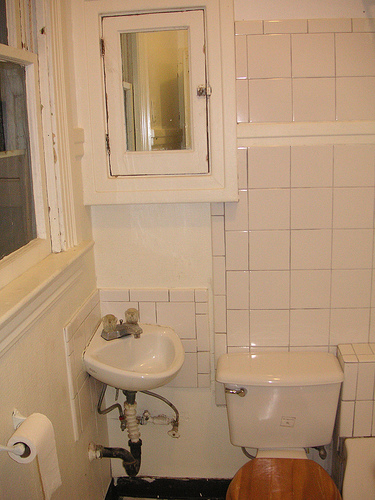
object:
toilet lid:
[226, 457, 342, 499]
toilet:
[215, 351, 343, 500]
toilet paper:
[5, 411, 63, 499]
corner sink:
[83, 316, 185, 391]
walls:
[64, 288, 212, 442]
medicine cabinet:
[71, 1, 239, 205]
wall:
[70, 1, 375, 474]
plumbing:
[96, 383, 179, 478]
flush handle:
[225, 387, 247, 398]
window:
[0, 1, 52, 289]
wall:
[0, 0, 111, 499]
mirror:
[119, 29, 191, 151]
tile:
[249, 270, 290, 310]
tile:
[63, 289, 103, 442]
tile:
[248, 188, 291, 231]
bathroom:
[0, 1, 373, 498]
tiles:
[195, 289, 208, 303]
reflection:
[249, 377, 281, 421]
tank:
[215, 352, 344, 448]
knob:
[125, 307, 139, 323]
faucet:
[101, 308, 143, 341]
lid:
[215, 350, 344, 386]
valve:
[167, 428, 180, 438]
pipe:
[239, 447, 255, 460]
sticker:
[280, 416, 296, 427]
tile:
[247, 145, 290, 189]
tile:
[290, 228, 332, 270]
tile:
[290, 188, 332, 230]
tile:
[333, 145, 375, 186]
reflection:
[120, 29, 192, 151]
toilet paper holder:
[0, 408, 26, 455]